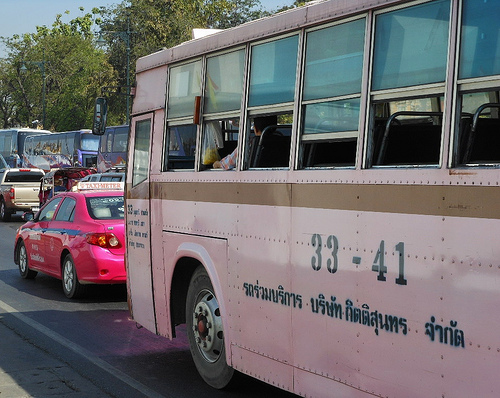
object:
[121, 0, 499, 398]
bus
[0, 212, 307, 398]
street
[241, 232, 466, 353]
writing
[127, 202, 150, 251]
writing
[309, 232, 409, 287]
33-41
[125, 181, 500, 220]
gold stripe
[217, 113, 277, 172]
person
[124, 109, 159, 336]
door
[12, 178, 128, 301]
taxi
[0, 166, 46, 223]
truck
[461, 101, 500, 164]
seats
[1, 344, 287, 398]
shadow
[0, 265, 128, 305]
shadow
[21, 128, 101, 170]
buses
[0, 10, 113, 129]
trees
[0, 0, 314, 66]
sky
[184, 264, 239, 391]
tire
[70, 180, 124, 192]
sign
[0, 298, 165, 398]
white line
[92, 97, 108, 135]
mirror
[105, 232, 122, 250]
rear lights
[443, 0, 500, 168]
windows